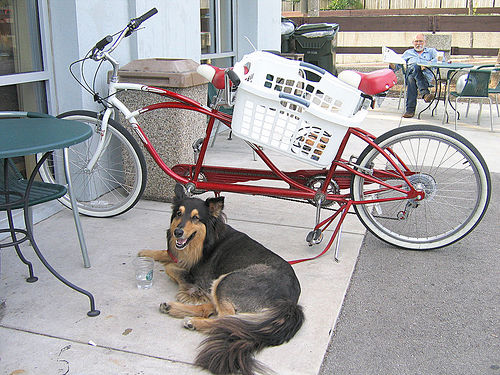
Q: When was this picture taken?
A: At daytime.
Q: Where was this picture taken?
A: On the sidewalk.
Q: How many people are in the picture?
A: One person.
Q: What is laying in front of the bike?
A: A dog.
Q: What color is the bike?
A: Red.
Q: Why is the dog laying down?
A: To rest.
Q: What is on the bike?
A: A laundry basket.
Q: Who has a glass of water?
A: The dog.